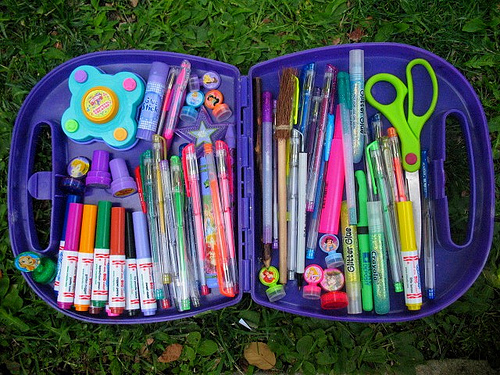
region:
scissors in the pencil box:
[368, 54, 442, 259]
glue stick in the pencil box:
[138, 55, 165, 141]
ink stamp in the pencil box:
[83, 147, 110, 186]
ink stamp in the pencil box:
[108, 156, 135, 198]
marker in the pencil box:
[56, 202, 82, 307]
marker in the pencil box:
[77, 203, 97, 315]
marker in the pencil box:
[92, 201, 108, 300]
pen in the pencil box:
[152, 134, 172, 292]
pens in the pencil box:
[204, 142, 238, 302]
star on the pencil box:
[174, 106, 228, 148]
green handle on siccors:
[365, 60, 450, 127]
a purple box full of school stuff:
[1, 41, 494, 336]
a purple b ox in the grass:
[0, 1, 492, 369]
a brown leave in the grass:
[237, 335, 292, 371]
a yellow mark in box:
[395, 199, 428, 313]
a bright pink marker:
[314, 132, 346, 238]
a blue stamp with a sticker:
[312, 228, 345, 268]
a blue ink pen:
[418, 142, 437, 307]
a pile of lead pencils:
[147, 130, 248, 310]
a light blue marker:
[132, 204, 157, 314]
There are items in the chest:
[26, 32, 465, 336]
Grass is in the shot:
[194, 328, 348, 364]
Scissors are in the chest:
[345, 48, 465, 303]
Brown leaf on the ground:
[233, 335, 288, 374]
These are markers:
[19, 206, 183, 326]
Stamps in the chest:
[297, 235, 367, 331]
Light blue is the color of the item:
[55, 56, 160, 161]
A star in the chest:
[177, 105, 237, 160]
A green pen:
[352, 168, 374, 310]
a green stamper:
[259, 264, 285, 302]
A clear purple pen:
[261, 90, 273, 245]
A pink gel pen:
[180, 141, 207, 296]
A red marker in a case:
[110, 201, 123, 313]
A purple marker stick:
[138, 59, 168, 137]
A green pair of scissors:
[365, 57, 440, 261]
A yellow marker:
[395, 198, 422, 310]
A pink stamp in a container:
[302, 263, 323, 299]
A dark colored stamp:
[62, 154, 89, 191]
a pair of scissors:
[360, 57, 448, 286]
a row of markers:
[53, 195, 175, 320]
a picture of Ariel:
[253, 265, 276, 287]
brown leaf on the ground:
[238, 341, 286, 373]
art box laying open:
[13, 40, 498, 335]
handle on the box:
[441, 112, 494, 251]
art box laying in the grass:
[9, 31, 484, 341]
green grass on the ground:
[0, 0, 499, 374]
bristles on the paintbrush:
[273, 66, 295, 139]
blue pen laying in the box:
[418, 150, 442, 296]